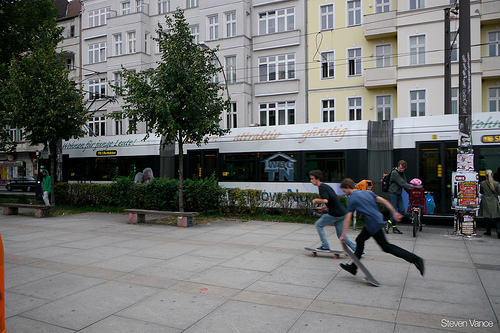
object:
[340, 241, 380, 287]
skateboard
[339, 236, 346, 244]
hand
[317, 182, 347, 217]
shirt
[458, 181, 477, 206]
sign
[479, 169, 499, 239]
woman